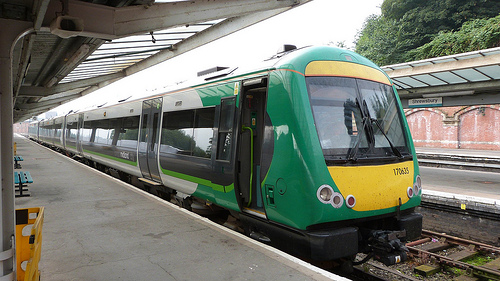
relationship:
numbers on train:
[390, 165, 410, 176] [26, 43, 427, 261]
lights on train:
[317, 186, 355, 207] [26, 43, 427, 261]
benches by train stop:
[14, 151, 27, 192] [14, 130, 304, 277]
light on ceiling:
[54, 41, 92, 79] [12, 6, 292, 112]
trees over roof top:
[359, 3, 483, 53] [390, 50, 483, 88]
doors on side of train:
[134, 96, 164, 185] [26, 43, 427, 261]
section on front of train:
[330, 162, 411, 209] [26, 43, 427, 261]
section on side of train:
[263, 72, 334, 237] [26, 43, 427, 261]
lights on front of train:
[314, 181, 412, 202] [26, 43, 427, 261]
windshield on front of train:
[303, 75, 414, 167] [26, 43, 427, 261]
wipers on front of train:
[345, 117, 404, 162] [26, 43, 427, 261]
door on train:
[235, 80, 264, 213] [26, 43, 427, 261]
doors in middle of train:
[144, 95, 166, 182] [29, 52, 424, 247]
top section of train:
[30, 56, 310, 107] [26, 43, 427, 261]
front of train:
[311, 213, 429, 266] [26, 43, 427, 261]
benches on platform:
[14, 151, 30, 196] [11, 131, 343, 278]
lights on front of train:
[345, 194, 356, 208] [56, 38, 419, 278]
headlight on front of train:
[328, 190, 346, 209] [62, 54, 407, 258]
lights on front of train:
[316, 184, 334, 204] [48, 70, 453, 252]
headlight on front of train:
[403, 182, 422, 204] [64, 44, 461, 269]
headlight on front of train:
[404, 177, 425, 202] [56, 38, 419, 278]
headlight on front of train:
[410, 170, 422, 185] [20, 52, 387, 269]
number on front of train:
[388, 161, 415, 181] [43, 39, 442, 264]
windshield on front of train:
[309, 80, 407, 175] [63, 57, 453, 277]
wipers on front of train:
[336, 101, 389, 151] [56, 38, 419, 278]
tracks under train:
[366, 224, 485, 275] [66, 21, 455, 278]